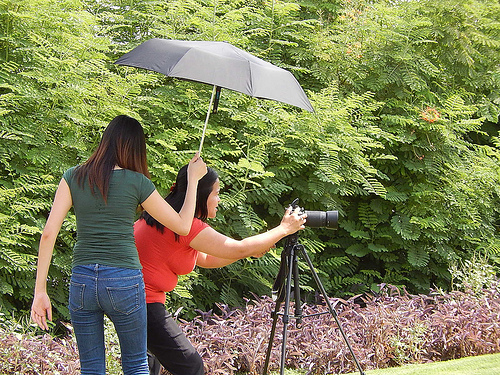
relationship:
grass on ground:
[392, 358, 497, 374] [238, 350, 479, 373]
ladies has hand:
[34, 110, 208, 374] [27, 292, 55, 334]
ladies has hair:
[34, 110, 208, 374] [72, 114, 150, 204]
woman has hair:
[130, 152, 306, 373] [139, 163, 219, 242]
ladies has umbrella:
[34, 110, 208, 374] [112, 24, 327, 138]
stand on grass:
[259, 229, 364, 374] [280, 354, 484, 373]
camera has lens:
[277, 200, 342, 236] [304, 210, 337, 225]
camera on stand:
[270, 196, 341, 304] [259, 229, 364, 374]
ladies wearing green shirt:
[34, 110, 208, 374] [63, 169, 157, 267]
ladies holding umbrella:
[34, 110, 208, 374] [113, 36, 315, 116]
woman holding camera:
[130, 152, 306, 373] [292, 199, 348, 241]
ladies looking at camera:
[34, 110, 294, 374] [288, 199, 343, 236]